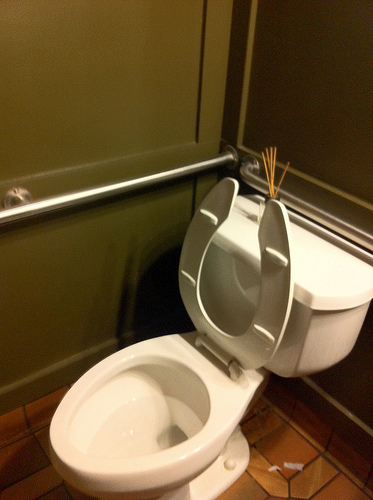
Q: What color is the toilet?
A: White.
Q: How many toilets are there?
A: 1.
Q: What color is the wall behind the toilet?
A: Green.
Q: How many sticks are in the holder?
A: 5.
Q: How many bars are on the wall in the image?
A: 2.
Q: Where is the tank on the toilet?
A: On the back.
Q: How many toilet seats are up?
A: 1.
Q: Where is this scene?
A: A bathroom.